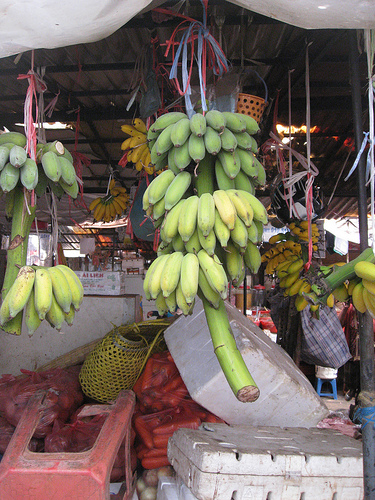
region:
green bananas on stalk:
[123, 94, 253, 334]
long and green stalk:
[209, 274, 250, 393]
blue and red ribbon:
[139, 3, 230, 111]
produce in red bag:
[141, 364, 212, 485]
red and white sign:
[64, 271, 132, 299]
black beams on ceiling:
[58, 39, 137, 147]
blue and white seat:
[316, 361, 342, 414]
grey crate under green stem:
[155, 417, 373, 497]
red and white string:
[11, 72, 64, 160]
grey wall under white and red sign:
[0, 289, 137, 394]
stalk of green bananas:
[139, 105, 270, 407]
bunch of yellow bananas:
[83, 174, 131, 224]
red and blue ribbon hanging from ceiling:
[149, 4, 230, 116]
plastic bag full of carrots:
[131, 355, 225, 471]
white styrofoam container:
[162, 417, 368, 498]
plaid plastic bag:
[265, 280, 355, 368]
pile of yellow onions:
[133, 463, 168, 499]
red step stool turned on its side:
[2, 386, 133, 499]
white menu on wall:
[65, 270, 122, 295]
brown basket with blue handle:
[234, 66, 271, 124]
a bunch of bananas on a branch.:
[139, 108, 270, 404]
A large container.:
[158, 416, 366, 498]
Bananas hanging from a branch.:
[0, 258, 93, 341]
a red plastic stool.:
[0, 383, 155, 496]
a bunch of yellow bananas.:
[112, 112, 161, 190]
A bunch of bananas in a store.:
[262, 194, 372, 331]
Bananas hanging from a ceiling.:
[85, 176, 133, 226]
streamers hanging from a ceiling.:
[151, 3, 245, 133]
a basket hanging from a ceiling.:
[227, 63, 278, 136]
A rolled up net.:
[73, 312, 166, 405]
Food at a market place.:
[0, 2, 371, 497]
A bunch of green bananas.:
[142, 105, 267, 399]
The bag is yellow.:
[72, 317, 172, 401]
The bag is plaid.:
[264, 289, 350, 365]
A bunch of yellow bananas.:
[262, 240, 298, 264]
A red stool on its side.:
[0, 383, 145, 496]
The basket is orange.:
[233, 90, 268, 122]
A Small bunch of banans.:
[0, 256, 82, 335]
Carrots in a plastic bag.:
[135, 350, 186, 407]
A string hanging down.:
[297, 50, 315, 264]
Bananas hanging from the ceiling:
[12, 90, 370, 342]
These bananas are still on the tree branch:
[150, 107, 271, 413]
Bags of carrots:
[0, 351, 184, 467]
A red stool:
[10, 388, 138, 498]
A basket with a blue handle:
[232, 61, 276, 118]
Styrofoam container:
[171, 410, 359, 499]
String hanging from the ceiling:
[270, 53, 326, 245]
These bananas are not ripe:
[142, 113, 274, 311]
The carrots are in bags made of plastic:
[15, 359, 193, 461]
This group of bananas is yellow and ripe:
[87, 181, 132, 220]